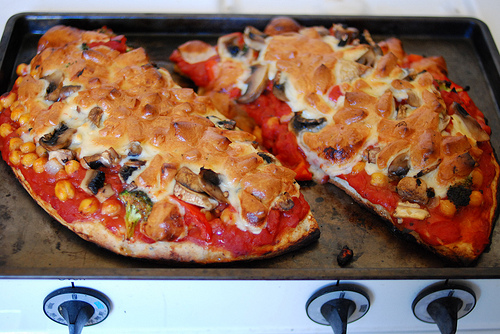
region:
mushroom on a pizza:
[33, 118, 79, 149]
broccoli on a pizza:
[118, 184, 171, 236]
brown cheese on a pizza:
[108, 120, 155, 146]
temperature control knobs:
[14, 267, 484, 332]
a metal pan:
[322, 196, 374, 253]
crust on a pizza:
[105, 210, 330, 265]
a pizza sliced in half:
[40, 25, 490, 246]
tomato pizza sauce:
[236, 86, 318, 183]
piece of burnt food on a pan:
[330, 237, 382, 270]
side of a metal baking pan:
[17, 5, 181, 42]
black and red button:
[336, 244, 371, 268]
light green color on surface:
[127, 287, 302, 332]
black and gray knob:
[307, 284, 369, 331]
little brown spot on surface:
[6, 217, 31, 259]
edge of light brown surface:
[145, 267, 212, 282]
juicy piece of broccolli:
[110, 187, 156, 233]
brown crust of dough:
[284, 211, 324, 245]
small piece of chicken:
[168, 171, 224, 217]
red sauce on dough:
[193, 209, 276, 247]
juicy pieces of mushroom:
[218, 31, 274, 104]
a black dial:
[39, 284, 112, 332]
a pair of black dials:
[303, 279, 483, 332]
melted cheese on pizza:
[34, 19, 299, 245]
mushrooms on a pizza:
[40, 122, 117, 199]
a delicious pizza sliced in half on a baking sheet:
[12, 18, 489, 266]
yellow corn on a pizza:
[1, 125, 121, 230]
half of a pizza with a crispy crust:
[170, 19, 494, 264]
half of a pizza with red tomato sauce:
[8, 21, 323, 263]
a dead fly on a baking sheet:
[329, 241, 366, 271]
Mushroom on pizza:
[175, 165, 226, 204]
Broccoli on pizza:
[113, 190, 152, 237]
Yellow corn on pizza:
[4, 135, 91, 209]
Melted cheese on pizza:
[41, 37, 300, 214]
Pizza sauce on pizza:
[176, 210, 282, 257]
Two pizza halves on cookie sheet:
[1, 17, 496, 258]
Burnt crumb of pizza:
[330, 241, 365, 261]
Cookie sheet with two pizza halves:
[3, 7, 498, 279]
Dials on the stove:
[21, 278, 481, 330]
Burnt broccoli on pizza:
[441, 176, 473, 210]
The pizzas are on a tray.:
[7, 8, 498, 278]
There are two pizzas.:
[8, 12, 492, 266]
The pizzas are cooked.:
[9, 10, 495, 270]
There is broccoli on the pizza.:
[112, 184, 159, 239]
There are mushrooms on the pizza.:
[36, 117, 84, 152]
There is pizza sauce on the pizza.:
[172, 199, 319, 260]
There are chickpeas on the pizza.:
[7, 135, 51, 174]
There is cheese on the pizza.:
[47, 49, 286, 216]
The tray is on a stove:
[2, 12, 494, 330]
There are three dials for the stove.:
[4, 277, 496, 332]